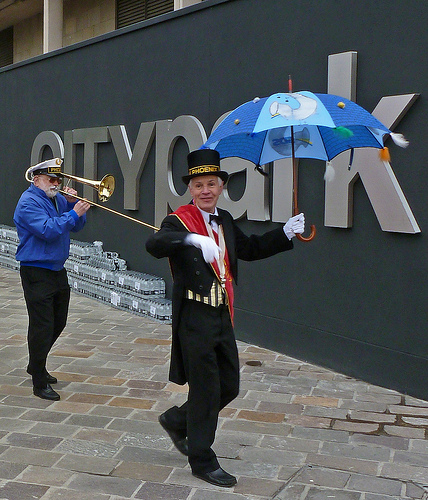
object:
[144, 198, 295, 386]
black coat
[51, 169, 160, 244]
trombone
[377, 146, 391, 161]
feather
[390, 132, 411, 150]
feather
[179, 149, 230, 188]
top hat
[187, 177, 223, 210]
head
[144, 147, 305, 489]
man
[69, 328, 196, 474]
cement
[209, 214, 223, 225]
tie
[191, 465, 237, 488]
shoes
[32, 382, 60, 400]
man's foot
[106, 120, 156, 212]
letters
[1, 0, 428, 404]
sign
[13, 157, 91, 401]
man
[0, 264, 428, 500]
ground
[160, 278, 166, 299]
bottles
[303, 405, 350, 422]
brick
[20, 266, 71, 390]
black pants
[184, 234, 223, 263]
gloves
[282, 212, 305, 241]
gloves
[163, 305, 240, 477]
pants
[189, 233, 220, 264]
hand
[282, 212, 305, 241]
hand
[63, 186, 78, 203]
hand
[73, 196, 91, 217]
hand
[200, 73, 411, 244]
umbrella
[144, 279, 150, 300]
bottles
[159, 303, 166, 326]
bottles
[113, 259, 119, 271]
bottles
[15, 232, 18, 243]
bottles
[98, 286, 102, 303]
bottles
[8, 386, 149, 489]
street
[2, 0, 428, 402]
wall